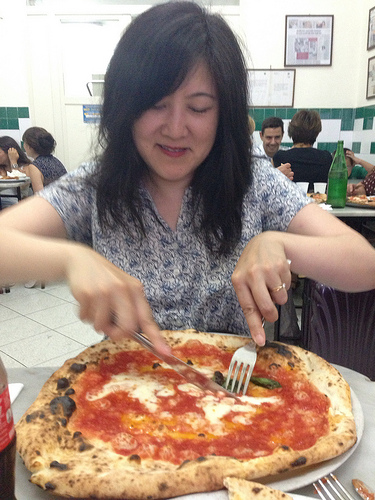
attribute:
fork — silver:
[135, 297, 291, 412]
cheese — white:
[91, 362, 280, 426]